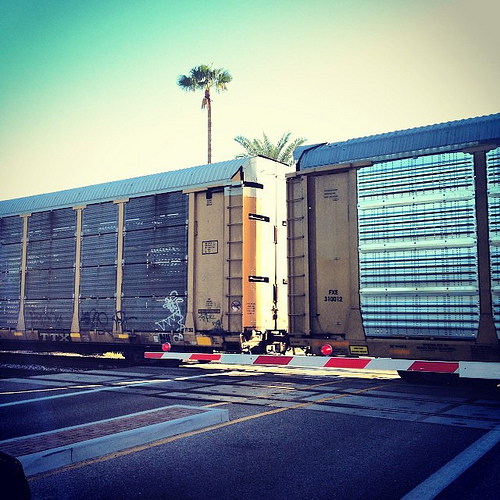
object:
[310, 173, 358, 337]
wall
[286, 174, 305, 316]
metal rungs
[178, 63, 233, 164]
tree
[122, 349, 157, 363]
train wheel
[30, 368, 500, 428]
sidewalk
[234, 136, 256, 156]
leaf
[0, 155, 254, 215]
roof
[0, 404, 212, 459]
red bricks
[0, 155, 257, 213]
aluminum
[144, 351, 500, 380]
crossing bar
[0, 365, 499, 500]
street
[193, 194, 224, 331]
door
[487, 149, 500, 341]
siding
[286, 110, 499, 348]
car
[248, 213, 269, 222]
window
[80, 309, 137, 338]
grafitti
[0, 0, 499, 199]
sky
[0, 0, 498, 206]
cloud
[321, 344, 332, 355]
light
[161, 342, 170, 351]
light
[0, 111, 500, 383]
train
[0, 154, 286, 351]
cabin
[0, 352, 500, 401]
track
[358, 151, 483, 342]
panel